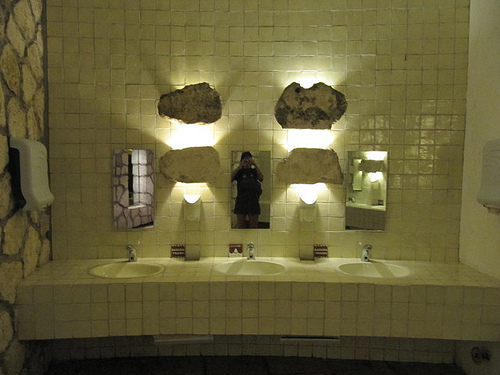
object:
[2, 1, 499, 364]
wall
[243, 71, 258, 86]
tiles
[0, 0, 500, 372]
bathroom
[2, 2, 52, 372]
rock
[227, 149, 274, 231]
mirror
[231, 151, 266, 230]
reflection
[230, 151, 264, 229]
camera man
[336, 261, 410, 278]
sink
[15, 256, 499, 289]
countertop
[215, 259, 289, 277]
sink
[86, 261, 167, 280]
sink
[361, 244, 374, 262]
faucet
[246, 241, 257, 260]
faucet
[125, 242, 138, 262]
faucet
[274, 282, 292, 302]
tile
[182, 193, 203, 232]
light fixture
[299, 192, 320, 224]
light fixture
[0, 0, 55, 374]
wall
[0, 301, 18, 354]
rocks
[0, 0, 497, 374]
photo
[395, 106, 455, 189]
light reflection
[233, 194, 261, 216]
shorts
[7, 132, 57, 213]
towel dispenser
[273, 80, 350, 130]
rock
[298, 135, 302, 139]
lights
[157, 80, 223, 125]
rock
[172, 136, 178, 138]
lights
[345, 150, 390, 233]
mirror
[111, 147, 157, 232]
mirror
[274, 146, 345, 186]
rock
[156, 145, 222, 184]
rock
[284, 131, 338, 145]
light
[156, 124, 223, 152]
light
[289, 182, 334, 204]
light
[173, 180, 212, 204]
light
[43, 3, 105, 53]
part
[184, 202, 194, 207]
part